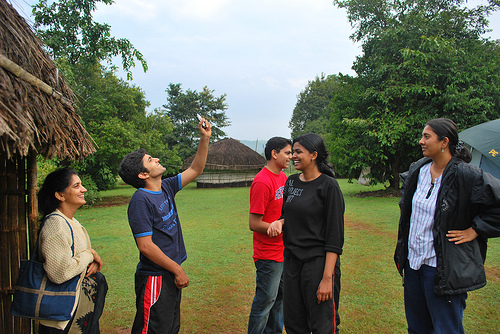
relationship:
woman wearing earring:
[386, 117, 484, 329] [439, 147, 449, 157]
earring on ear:
[437, 145, 447, 157] [441, 134, 448, 152]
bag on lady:
[8, 209, 78, 324] [34, 163, 105, 330]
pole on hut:
[0, 130, 12, 330] [4, 5, 86, 333]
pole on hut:
[9, 142, 28, 327] [4, 5, 86, 333]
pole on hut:
[19, 140, 26, 262] [4, 5, 86, 333]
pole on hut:
[21, 147, 36, 258] [4, 5, 86, 333]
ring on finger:
[305, 277, 346, 305] [318, 286, 327, 304]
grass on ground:
[197, 189, 242, 269] [40, 174, 498, 328]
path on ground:
[342, 209, 399, 246] [91, 193, 498, 331]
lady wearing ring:
[10, 168, 108, 334] [88, 256, 132, 286]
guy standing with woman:
[248, 135, 289, 332] [269, 134, 344, 333]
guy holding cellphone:
[114, 114, 215, 332] [191, 107, 217, 139]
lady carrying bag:
[10, 168, 108, 334] [10, 214, 109, 332]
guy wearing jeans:
[249, 136, 292, 332] [248, 264, 290, 304]